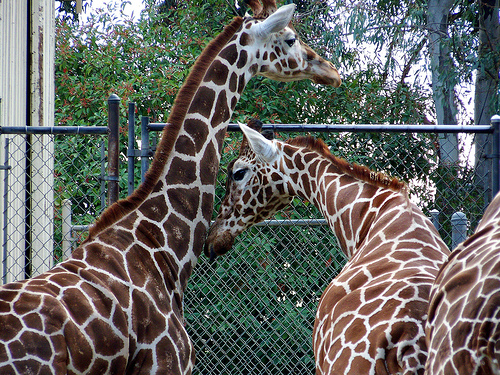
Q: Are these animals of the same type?
A: Yes, all the animals are giraffes.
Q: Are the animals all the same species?
A: Yes, all the animals are giraffes.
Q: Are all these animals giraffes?
A: Yes, all the animals are giraffes.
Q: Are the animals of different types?
A: No, all the animals are giraffes.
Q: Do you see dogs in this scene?
A: No, there are no dogs.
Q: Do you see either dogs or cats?
A: No, there are no dogs or cats.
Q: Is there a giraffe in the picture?
A: Yes, there is a giraffe.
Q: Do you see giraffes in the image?
A: Yes, there is a giraffe.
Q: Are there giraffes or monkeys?
A: Yes, there is a giraffe.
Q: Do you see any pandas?
A: No, there are no pandas.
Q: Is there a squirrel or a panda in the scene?
A: No, there are no pandas or squirrels.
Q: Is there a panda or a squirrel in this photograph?
A: No, there are no pandas or squirrels.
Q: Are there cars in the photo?
A: No, there are no cars.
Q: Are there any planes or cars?
A: No, there are no cars or planes.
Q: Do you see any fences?
A: Yes, there is a fence.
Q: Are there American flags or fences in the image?
A: Yes, there is a fence.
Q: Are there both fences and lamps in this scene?
A: No, there is a fence but no lamps.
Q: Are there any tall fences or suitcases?
A: Yes, there is a tall fence.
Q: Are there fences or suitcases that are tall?
A: Yes, the fence is tall.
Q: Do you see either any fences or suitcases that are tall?
A: Yes, the fence is tall.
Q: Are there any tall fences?
A: Yes, there is a tall fence.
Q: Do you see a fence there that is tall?
A: Yes, there is a tall fence.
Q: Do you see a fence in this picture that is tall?
A: Yes, there is a fence that is tall.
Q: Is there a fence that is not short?
A: Yes, there is a tall fence.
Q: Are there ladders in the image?
A: No, there are no ladders.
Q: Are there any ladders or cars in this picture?
A: No, there are no ladders or cars.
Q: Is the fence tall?
A: Yes, the fence is tall.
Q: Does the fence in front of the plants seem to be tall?
A: Yes, the fence is tall.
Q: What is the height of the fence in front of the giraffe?
A: The fence is tall.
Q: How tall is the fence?
A: The fence is tall.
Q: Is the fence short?
A: No, the fence is tall.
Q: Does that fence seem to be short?
A: No, the fence is tall.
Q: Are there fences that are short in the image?
A: No, there is a fence but it is tall.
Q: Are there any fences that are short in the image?
A: No, there is a fence but it is tall.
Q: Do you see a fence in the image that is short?
A: No, there is a fence but it is tall.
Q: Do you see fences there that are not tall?
A: No, there is a fence but it is tall.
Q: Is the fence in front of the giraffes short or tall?
A: The fence is tall.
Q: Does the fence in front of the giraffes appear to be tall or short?
A: The fence is tall.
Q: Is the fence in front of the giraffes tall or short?
A: The fence is tall.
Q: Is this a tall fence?
A: Yes, this is a tall fence.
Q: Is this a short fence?
A: No, this is a tall fence.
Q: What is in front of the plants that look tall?
A: The fence is in front of the plants.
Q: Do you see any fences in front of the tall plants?
A: Yes, there is a fence in front of the plants.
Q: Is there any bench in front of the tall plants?
A: No, there is a fence in front of the plants.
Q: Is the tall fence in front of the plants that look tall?
A: Yes, the fence is in front of the plants.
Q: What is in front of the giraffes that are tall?
A: The fence is in front of the giraffes.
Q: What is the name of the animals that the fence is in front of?
A: The animals are giraffes.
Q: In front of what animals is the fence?
A: The fence is in front of the giraffes.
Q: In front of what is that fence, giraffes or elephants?
A: The fence is in front of giraffes.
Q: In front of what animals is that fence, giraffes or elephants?
A: The fence is in front of giraffes.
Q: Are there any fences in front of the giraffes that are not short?
A: Yes, there is a fence in front of the giraffes.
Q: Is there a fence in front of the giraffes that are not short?
A: Yes, there is a fence in front of the giraffes.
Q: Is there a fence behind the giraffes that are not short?
A: No, the fence is in front of the giraffes.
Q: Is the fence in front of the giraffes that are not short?
A: Yes, the fence is in front of the giraffes.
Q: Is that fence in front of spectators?
A: No, the fence is in front of the giraffes.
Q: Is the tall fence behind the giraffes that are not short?
A: No, the fence is in front of the giraffes.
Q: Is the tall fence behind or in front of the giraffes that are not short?
A: The fence is in front of the giraffes.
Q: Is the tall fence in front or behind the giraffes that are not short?
A: The fence is in front of the giraffes.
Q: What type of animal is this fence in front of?
A: The fence is in front of the giraffe.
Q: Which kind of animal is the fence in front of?
A: The fence is in front of the giraffe.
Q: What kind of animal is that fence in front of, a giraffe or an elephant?
A: The fence is in front of a giraffe.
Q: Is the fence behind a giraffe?
A: No, the fence is in front of a giraffe.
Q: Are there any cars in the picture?
A: No, there are no cars.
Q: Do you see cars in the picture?
A: No, there are no cars.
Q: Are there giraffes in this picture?
A: Yes, there are giraffes.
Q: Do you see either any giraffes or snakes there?
A: Yes, there are giraffes.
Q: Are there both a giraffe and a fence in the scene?
A: Yes, there are both a giraffe and a fence.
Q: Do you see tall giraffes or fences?
A: Yes, there are tall giraffes.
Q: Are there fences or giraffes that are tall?
A: Yes, the giraffes are tall.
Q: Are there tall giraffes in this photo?
A: Yes, there are tall giraffes.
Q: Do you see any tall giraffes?
A: Yes, there are tall giraffes.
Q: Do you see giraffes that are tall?
A: Yes, there are giraffes that are tall.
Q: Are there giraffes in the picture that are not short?
A: Yes, there are tall giraffes.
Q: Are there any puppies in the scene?
A: No, there are no puppies.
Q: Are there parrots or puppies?
A: No, there are no puppies or parrots.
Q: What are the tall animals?
A: The animals are giraffes.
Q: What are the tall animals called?
A: The animals are giraffes.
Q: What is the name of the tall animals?
A: The animals are giraffes.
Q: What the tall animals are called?
A: The animals are giraffes.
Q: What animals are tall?
A: The animals are giraffes.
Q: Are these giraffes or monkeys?
A: These are giraffes.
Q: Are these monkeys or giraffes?
A: These are giraffes.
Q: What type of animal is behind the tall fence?
A: The animals are giraffes.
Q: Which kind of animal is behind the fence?
A: The animals are giraffes.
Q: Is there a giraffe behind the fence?
A: Yes, there are giraffes behind the fence.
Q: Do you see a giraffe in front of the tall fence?
A: No, the giraffes are behind the fence.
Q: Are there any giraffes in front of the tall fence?
A: No, the giraffes are behind the fence.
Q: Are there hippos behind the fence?
A: No, there are giraffes behind the fence.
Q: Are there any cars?
A: No, there are no cars.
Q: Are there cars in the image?
A: No, there are no cars.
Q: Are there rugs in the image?
A: No, there are no rugs.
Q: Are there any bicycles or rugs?
A: No, there are no rugs or bicycles.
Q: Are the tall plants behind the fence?
A: Yes, the plants are behind the fence.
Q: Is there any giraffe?
A: Yes, there is a giraffe.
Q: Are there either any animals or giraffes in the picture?
A: Yes, there is a giraffe.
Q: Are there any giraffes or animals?
A: Yes, there is a giraffe.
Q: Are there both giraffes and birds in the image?
A: No, there is a giraffe but no birds.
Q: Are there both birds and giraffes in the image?
A: No, there is a giraffe but no birds.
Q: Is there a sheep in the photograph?
A: No, there is no sheep.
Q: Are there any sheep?
A: No, there are no sheep.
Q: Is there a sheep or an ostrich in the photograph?
A: No, there are no sheep or ostriches.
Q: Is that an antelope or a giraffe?
A: That is a giraffe.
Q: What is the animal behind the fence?
A: The animal is a giraffe.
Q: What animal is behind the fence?
A: The animal is a giraffe.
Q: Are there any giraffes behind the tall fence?
A: Yes, there is a giraffe behind the fence.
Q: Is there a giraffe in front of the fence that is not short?
A: No, the giraffe is behind the fence.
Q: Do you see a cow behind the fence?
A: No, there is a giraffe behind the fence.